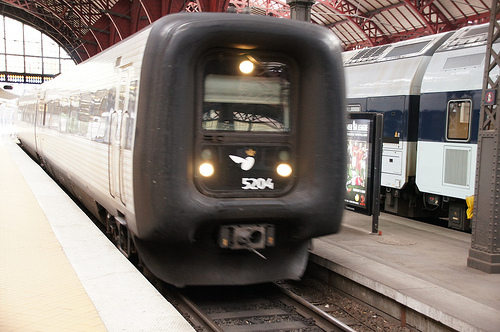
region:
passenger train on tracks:
[9, 12, 438, 328]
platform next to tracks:
[0, 137, 192, 330]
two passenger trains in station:
[2, 13, 497, 285]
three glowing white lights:
[195, 58, 295, 178]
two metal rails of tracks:
[173, 283, 361, 330]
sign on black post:
[343, 110, 385, 235]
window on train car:
[416, 21, 479, 231]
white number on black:
[242, 176, 274, 190]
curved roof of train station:
[1, 0, 498, 62]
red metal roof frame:
[319, 1, 456, 48]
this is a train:
[116, 6, 346, 251]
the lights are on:
[205, 163, 305, 183]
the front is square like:
[158, 18, 334, 221]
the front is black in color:
[307, 59, 347, 142]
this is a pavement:
[390, 217, 460, 282]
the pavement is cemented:
[380, 225, 448, 275]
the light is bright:
[235, 60, 262, 76]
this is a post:
[473, 156, 495, 264]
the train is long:
[35, 56, 117, 163]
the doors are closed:
[105, 71, 137, 188]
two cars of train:
[344, 21, 497, 229]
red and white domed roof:
[0, 1, 497, 65]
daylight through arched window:
[0, 11, 86, 93]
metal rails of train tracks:
[185, 283, 352, 329]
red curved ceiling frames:
[328, 2, 448, 44]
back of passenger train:
[135, 17, 348, 286]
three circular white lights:
[197, 58, 292, 178]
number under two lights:
[197, 161, 291, 192]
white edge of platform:
[4, 139, 191, 327]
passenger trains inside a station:
[6, 6, 494, 323]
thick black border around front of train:
[130, 10, 345, 285]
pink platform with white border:
[0, 120, 192, 326]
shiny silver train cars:
[7, 25, 147, 241]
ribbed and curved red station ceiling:
[0, 0, 490, 72]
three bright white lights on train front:
[190, 55, 291, 176]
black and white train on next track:
[340, 20, 486, 235]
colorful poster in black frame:
[346, 110, 381, 235]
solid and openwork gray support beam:
[462, 1, 494, 266]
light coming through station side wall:
[1, 10, 76, 85]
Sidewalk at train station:
[13, 237, 52, 302]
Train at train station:
[108, 7, 383, 312]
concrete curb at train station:
[98, 275, 131, 318]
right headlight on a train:
[195, 152, 223, 187]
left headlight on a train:
[274, 157, 293, 186]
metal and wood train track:
[283, 292, 338, 330]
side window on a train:
[437, 97, 478, 154]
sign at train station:
[355, 101, 393, 242]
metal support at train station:
[457, 130, 499, 282]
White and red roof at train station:
[348, 11, 399, 38]